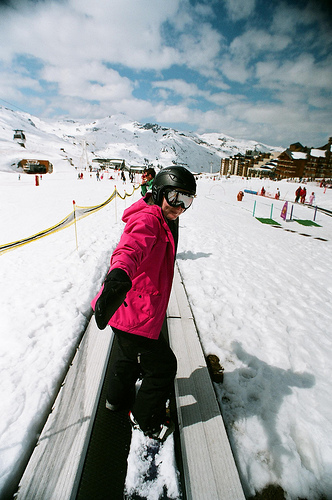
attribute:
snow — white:
[1, 107, 332, 497]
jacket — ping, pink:
[92, 193, 179, 340]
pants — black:
[111, 329, 178, 441]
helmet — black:
[146, 166, 199, 200]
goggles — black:
[166, 186, 196, 211]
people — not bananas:
[119, 159, 323, 212]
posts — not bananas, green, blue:
[249, 198, 320, 227]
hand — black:
[94, 271, 135, 331]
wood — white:
[12, 297, 255, 499]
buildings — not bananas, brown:
[263, 140, 330, 178]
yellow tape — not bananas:
[1, 172, 136, 269]